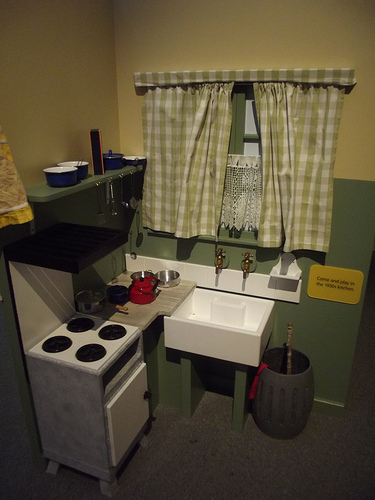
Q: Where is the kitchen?
A: In the corner.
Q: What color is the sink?
A: White.